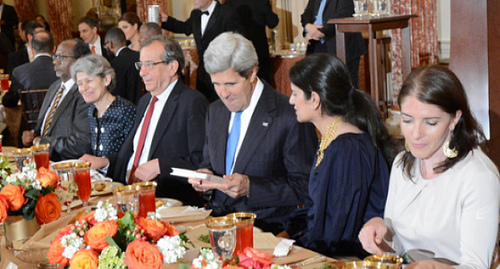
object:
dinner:
[0, 141, 408, 269]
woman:
[358, 64, 500, 267]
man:
[186, 31, 318, 237]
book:
[169, 167, 231, 186]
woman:
[275, 53, 396, 259]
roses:
[33, 191, 61, 227]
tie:
[225, 110, 245, 176]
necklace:
[312, 115, 345, 170]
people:
[19, 37, 92, 162]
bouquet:
[0, 164, 62, 226]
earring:
[442, 132, 461, 159]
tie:
[201, 9, 210, 16]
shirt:
[306, 0, 329, 45]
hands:
[213, 172, 249, 199]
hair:
[203, 30, 260, 79]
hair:
[396, 65, 489, 185]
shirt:
[384, 141, 500, 269]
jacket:
[196, 77, 319, 236]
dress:
[282, 131, 389, 259]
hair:
[69, 54, 118, 93]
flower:
[44, 200, 186, 269]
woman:
[68, 55, 139, 175]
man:
[76, 35, 210, 209]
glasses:
[134, 60, 169, 71]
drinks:
[206, 216, 237, 263]